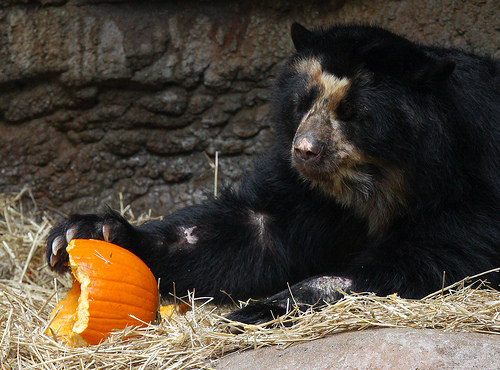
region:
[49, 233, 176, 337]
cut piece of orange pumpkin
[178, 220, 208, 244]
small white spot on bear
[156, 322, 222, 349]
brown straw on the ground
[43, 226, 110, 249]
brown claws on bear's hand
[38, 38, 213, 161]
black rock formation against the wall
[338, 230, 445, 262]
black fur on bear's body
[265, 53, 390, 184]
white and brown color on bear's face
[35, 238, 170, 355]
This is a fruit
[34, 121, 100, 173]
Section of a wall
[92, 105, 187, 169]
Section of a wall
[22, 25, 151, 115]
Section of a wall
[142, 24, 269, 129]
Section of a wall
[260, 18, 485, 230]
Head of an animal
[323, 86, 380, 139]
eye of an animal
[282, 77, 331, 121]
eye of an animal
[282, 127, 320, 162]
nose of an animal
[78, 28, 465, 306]
the bear is black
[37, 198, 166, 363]
pumpkin shell is orange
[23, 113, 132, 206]
Section of a wall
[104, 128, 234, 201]
Section of a wall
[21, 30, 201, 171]
Section of a wall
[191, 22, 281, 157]
Section of a wall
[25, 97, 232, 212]
Section of a wall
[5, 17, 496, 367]
a scene at the zoo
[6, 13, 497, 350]
a scene during the day time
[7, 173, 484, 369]
a yellow patch of hay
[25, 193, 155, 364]
an orange pumpkin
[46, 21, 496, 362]
a black bear holding on to a pumpkin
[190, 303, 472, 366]
a gray spot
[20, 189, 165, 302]
some bear claws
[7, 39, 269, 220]
a rocky background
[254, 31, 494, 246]
a tan face of bear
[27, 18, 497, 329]
something holding on a pumpkin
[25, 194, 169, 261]
Part of an animal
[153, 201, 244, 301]
Part of an animal